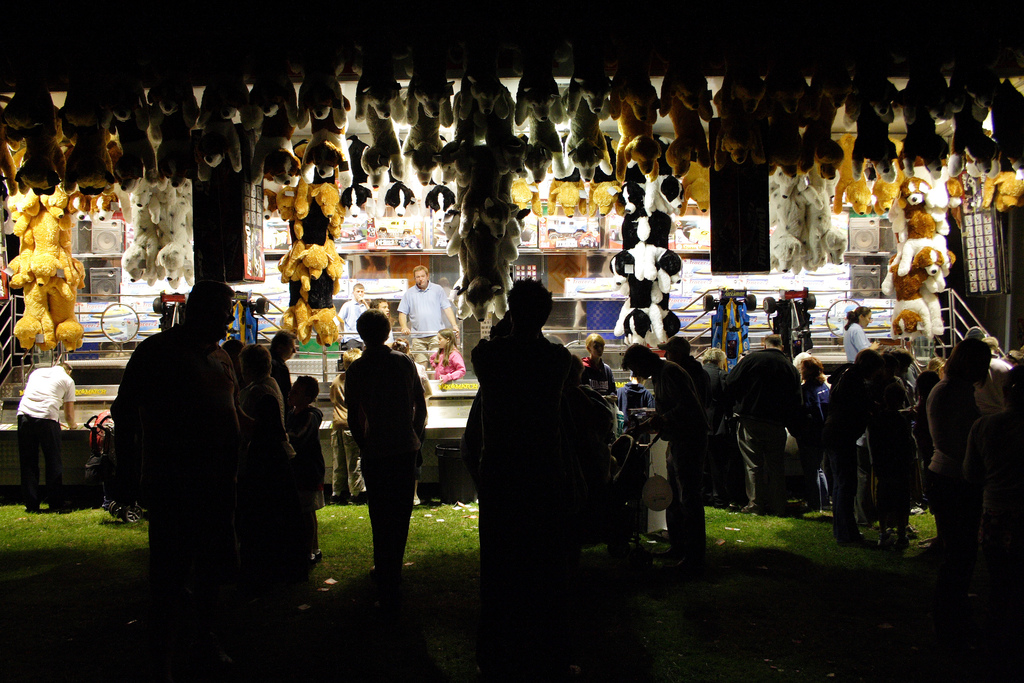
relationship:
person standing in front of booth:
[338, 309, 431, 562] [3, 9, 989, 502]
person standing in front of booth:
[463, 264, 589, 666] [3, 9, 989, 502]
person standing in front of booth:
[614, 340, 718, 570] [3, 9, 989, 502]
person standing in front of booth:
[109, 268, 256, 677] [3, 9, 989, 502]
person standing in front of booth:
[856, 346, 921, 548] [3, 9, 989, 502]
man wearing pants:
[0, 316, 104, 533] [7, 411, 62, 522]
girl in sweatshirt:
[426, 323, 474, 388] [430, 351, 467, 386]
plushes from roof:
[384, 63, 471, 226] [4, 1, 992, 88]